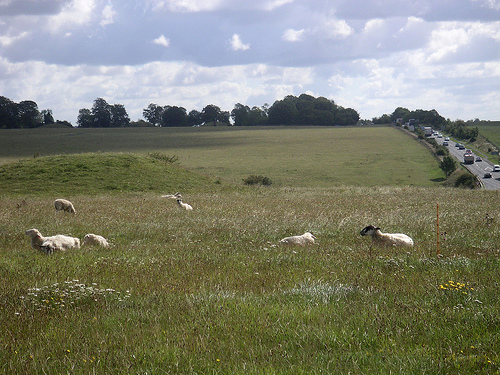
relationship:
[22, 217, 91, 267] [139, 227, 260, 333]
sheep on grass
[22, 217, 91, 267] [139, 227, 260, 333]
sheep lying on grass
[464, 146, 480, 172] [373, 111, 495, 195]
truck on highway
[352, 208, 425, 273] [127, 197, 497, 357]
sheep lying in field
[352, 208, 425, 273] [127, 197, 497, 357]
sheep in field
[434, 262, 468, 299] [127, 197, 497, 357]
flowers in field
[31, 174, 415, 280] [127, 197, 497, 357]
sheep in field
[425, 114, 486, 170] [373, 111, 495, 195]
cars on highway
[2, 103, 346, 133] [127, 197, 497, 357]
trees behind field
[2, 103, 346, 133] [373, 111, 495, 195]
trees near highway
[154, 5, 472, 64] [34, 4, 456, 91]
clouds in sky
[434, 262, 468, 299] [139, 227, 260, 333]
flowers in grass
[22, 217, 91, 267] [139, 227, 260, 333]
sheep sitting in grass